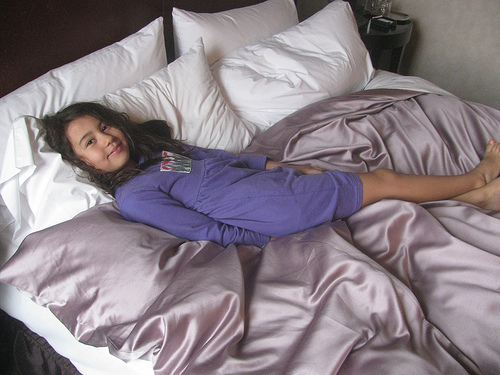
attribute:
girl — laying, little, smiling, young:
[45, 99, 496, 256]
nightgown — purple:
[132, 145, 367, 250]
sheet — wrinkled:
[182, 254, 455, 370]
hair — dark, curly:
[24, 105, 176, 179]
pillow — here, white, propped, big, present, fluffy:
[231, 4, 361, 125]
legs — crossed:
[341, 132, 499, 225]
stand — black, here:
[361, 10, 418, 64]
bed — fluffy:
[42, 40, 485, 367]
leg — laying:
[366, 184, 483, 236]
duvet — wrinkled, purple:
[302, 280, 387, 338]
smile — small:
[109, 138, 132, 157]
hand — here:
[269, 149, 327, 181]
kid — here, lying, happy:
[34, 87, 499, 265]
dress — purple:
[131, 173, 389, 238]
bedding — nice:
[274, 97, 464, 328]